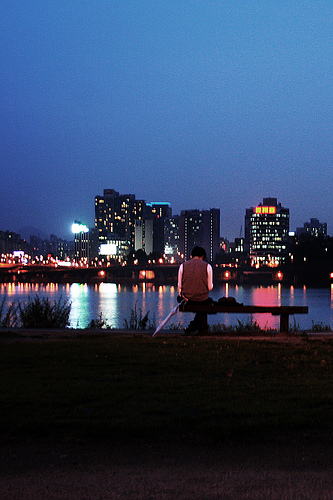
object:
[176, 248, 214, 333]
boy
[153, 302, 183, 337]
toy sword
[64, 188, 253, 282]
building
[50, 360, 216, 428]
grass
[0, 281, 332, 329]
water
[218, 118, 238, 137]
ground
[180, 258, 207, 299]
sweater vest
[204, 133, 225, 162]
ground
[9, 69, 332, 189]
sky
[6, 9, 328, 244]
background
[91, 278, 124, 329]
line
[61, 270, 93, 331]
line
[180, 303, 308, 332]
bench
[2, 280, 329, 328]
reflection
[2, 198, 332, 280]
lights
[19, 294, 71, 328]
foliage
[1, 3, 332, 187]
moonlight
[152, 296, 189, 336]
umbrella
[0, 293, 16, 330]
shrubs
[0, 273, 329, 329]
river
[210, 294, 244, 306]
clothing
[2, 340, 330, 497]
field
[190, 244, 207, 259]
head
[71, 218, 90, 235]
sign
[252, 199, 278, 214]
windows